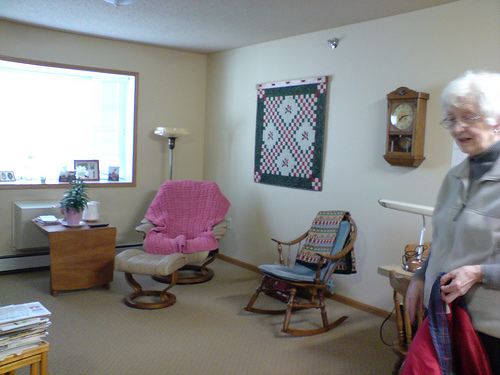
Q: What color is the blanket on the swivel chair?
A: Pink.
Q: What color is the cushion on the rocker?
A: Blue.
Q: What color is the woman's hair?
A: White.